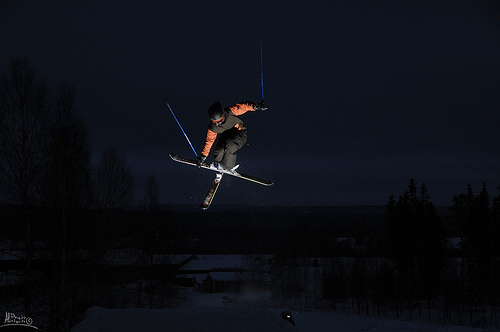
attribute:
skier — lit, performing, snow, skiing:
[192, 100, 270, 177]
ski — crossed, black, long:
[165, 147, 279, 195]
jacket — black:
[204, 101, 261, 158]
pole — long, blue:
[253, 31, 271, 115]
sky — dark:
[3, 4, 499, 196]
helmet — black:
[206, 102, 229, 129]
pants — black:
[209, 131, 249, 170]